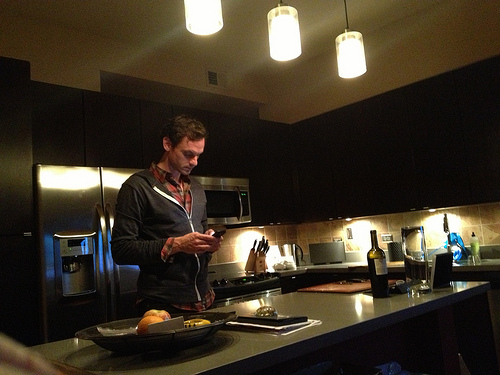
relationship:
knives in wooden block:
[251, 236, 272, 255] [244, 246, 267, 274]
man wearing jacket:
[110, 116, 224, 317] [111, 168, 211, 303]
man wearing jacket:
[110, 116, 224, 317] [107, 168, 211, 303]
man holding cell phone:
[110, 116, 224, 317] [212, 229, 227, 238]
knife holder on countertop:
[244, 235, 271, 276] [239, 244, 497, 277]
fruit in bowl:
[138, 309, 212, 332] [74, 309, 239, 354]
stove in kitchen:
[205, 261, 283, 305] [1, 1, 498, 375]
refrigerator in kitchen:
[36, 162, 149, 342] [1, 1, 498, 375]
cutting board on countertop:
[298, 276, 398, 295] [27, 278, 492, 372]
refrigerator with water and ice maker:
[36, 162, 149, 342] [52, 229, 100, 300]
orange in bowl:
[136, 315, 164, 335] [74, 309, 239, 354]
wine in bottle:
[368, 258, 389, 299] [365, 229, 390, 300]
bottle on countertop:
[468, 233, 482, 263] [239, 244, 497, 277]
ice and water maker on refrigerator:
[52, 229, 100, 300] [36, 162, 149, 342]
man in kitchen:
[110, 116, 224, 317] [1, 1, 498, 375]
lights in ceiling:
[183, 1, 368, 79] [1, 0, 457, 71]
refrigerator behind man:
[36, 162, 149, 342] [110, 116, 224, 317]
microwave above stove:
[186, 174, 253, 225] [205, 261, 283, 305]